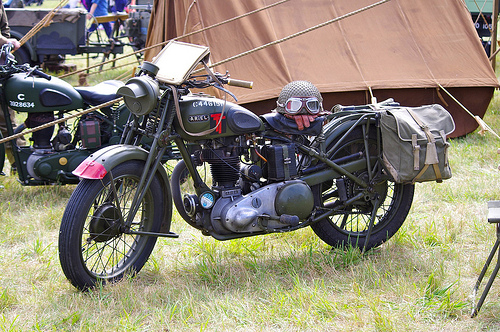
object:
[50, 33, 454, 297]
cycle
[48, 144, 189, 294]
wheel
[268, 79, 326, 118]
helmet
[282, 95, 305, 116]
goggles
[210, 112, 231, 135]
marks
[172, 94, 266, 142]
gas tank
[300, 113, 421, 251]
back wheel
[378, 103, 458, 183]
pack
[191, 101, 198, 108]
c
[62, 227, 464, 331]
grass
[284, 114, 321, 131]
glove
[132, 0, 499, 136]
tent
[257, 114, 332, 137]
seat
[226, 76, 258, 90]
handle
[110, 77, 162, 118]
headlight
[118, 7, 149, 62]
people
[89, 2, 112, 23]
shirt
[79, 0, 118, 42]
person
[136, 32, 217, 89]
windshield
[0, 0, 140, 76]
truck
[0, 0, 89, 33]
bed